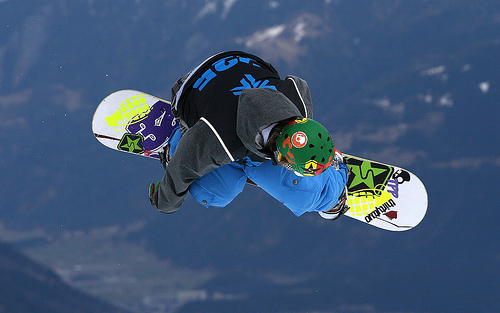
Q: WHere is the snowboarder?
A: In the air.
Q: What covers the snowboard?
A: Stickers.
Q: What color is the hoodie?
A: Grey.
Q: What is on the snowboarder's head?
A: A helmet.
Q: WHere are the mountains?
A: Underneath the snowboarder.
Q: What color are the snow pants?
A: Blue.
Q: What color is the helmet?
A: Green.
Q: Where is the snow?
A: On the mountaintops.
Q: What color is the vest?
A: Blue and black.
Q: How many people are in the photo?
A: One.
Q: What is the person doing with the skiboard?
A: Stunt jump.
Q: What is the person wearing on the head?
A: Helmet.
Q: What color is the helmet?
A: Green.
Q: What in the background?
A: Mountains.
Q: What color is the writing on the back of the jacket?
A: Blue.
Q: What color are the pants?
A: Blue.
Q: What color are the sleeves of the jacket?
A: Dark Grey.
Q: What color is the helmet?
A: Dark Green.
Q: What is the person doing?
A: Snowboarding.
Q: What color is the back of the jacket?
A: Black and blue.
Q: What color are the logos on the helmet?
A: Orange, White, Green, Black, Yellow, and Red.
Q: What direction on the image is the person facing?
A: Downward.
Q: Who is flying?
A: A person.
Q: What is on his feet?
A: Snow board.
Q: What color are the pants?
A: Blue.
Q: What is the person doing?
A: Falling.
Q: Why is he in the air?
A: Jumped.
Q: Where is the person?
A: In the air.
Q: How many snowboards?
A: 1.